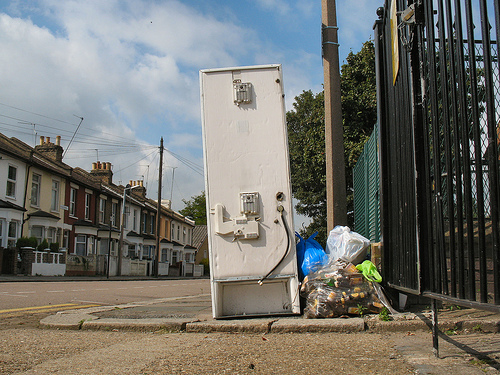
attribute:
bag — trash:
[301, 224, 381, 316]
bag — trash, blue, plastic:
[295, 225, 326, 275]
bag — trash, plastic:
[326, 221, 370, 262]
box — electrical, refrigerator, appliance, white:
[199, 63, 302, 319]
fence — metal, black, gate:
[373, 1, 499, 352]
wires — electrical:
[0, 100, 203, 183]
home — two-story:
[0, 134, 31, 279]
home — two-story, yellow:
[22, 147, 71, 275]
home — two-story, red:
[63, 169, 98, 273]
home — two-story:
[97, 176, 124, 276]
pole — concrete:
[319, 1, 348, 246]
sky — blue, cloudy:
[2, 1, 499, 208]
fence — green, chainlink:
[348, 124, 380, 243]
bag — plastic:
[301, 258, 381, 317]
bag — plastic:
[356, 258, 383, 282]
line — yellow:
[1, 300, 99, 317]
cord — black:
[258, 214, 291, 287]